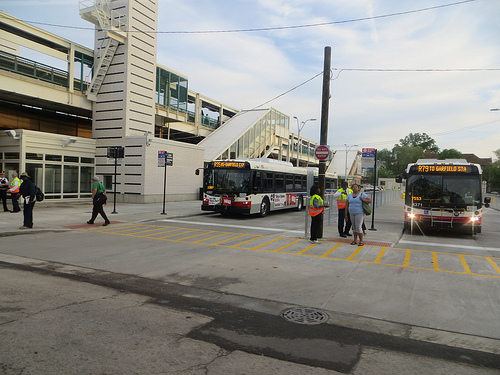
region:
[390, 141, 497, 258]
bus parked at bus stop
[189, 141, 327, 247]
bus parked at bus stop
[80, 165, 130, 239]
man walking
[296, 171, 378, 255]
people standing on crossing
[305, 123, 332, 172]
red circle sign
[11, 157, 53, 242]
man dressed in black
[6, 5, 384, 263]
cream building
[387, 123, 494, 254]
this is a bus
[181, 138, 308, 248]
this is a bus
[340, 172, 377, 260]
this is a person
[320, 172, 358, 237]
this is a person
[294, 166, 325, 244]
this is a person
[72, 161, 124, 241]
this is a person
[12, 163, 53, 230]
this is a person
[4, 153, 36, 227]
this is a person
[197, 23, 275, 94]
this is a cloud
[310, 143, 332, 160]
The sign is red and white in color.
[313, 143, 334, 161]
The sign is in English.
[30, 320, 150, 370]
The pavement is gray in color.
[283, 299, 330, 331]
The man hole cover is round.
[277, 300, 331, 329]
The man hole cover is made of steel.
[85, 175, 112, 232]
The man is walking.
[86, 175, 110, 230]
The man is wearing a green shirt.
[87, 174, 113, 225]
The man is carrying a black bag.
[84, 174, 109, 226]
The man is wearing black pants.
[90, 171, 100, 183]
The man has gray hair.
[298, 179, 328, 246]
orange and green vest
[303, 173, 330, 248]
orange and green vest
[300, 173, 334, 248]
orange and green vest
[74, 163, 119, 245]
the man is walking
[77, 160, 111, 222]
the man is walking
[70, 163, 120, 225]
the man is walking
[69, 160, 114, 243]
the man is walking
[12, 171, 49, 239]
this is a person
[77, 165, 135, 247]
this is a person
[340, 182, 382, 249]
this is a person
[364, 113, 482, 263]
this is a bus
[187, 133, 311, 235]
this is a bus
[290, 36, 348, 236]
this is a post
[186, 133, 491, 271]
the buses are parked